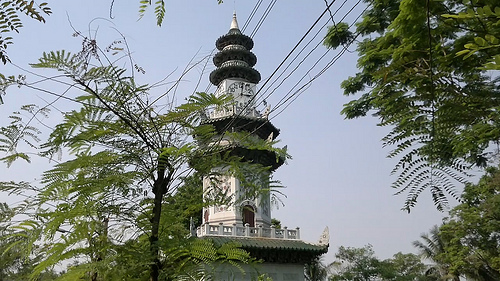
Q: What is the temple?
A: White and gray.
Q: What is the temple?
A: White and gray.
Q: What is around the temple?
A: Trees.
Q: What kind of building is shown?
A: Temple,.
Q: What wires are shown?
A: Power lines.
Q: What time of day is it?
A: Afternoon.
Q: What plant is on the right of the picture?
A: Tree.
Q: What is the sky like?
A: Clear.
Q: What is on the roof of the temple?
A: Railing.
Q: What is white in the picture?
A: The building.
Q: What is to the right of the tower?
A: Leaves.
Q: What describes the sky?
A: Clear blue.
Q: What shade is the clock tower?
A: White.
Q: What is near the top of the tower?
A: Power lines.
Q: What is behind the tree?
A: Power lines.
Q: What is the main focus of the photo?
A: The clock tower.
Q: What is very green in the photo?
A: Leaves.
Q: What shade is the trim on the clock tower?
A: Black.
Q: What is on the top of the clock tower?
A: A point.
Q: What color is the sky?
A: Blue.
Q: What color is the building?
A: White.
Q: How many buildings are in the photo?
A: 1.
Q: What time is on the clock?
A: 3:00.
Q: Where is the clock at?
A: On building.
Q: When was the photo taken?
A: Daytime.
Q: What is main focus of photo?
A: The building.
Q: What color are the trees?
A: Green.